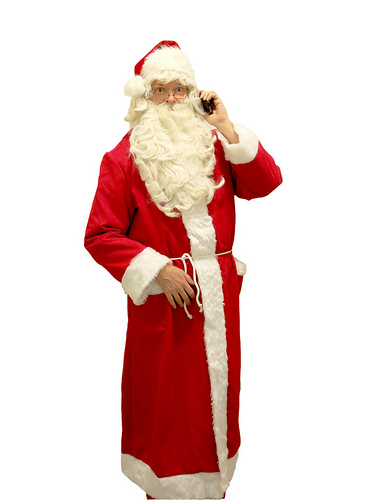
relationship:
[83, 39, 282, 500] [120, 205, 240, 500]
costume wearing faux fur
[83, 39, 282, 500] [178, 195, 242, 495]
costume wearing fur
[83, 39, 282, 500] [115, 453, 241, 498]
costume wearing fur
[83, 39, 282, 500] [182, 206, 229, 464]
costume wearing fur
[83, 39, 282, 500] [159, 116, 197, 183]
costume wearing fur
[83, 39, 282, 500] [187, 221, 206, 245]
costume wearing fur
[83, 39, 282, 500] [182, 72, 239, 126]
costume carrying cell phone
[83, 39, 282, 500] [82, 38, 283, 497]
costume wearing costume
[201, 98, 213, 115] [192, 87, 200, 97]
cell phone lifted to ear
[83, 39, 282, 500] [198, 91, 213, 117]
costume on phone